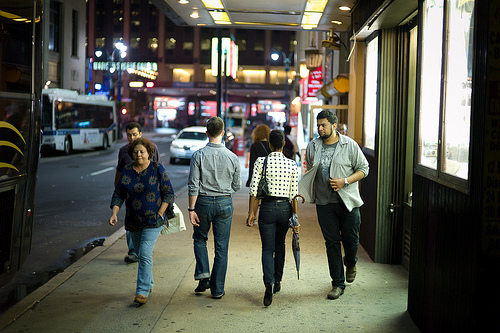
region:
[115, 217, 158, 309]
Person wearing blue pants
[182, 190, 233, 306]
Person wearing blue jeans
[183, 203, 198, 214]
Wrist watch on left wrist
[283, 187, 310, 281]
Woman carrying an umbrella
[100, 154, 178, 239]
Person wearing a blue sweater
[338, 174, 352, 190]
Silver watch on a man's wrist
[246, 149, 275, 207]
Woman wearing a purse on left shoulder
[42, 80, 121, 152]
White tour bus on a street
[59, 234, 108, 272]
Concrete curb on edge of sidewalk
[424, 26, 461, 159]
Light coming from inside a window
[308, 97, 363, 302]
man wearing a t shirt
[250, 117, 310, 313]
woman wearing white shirt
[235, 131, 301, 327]
woman wearing blue jeans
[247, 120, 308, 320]
woman holding an umbrella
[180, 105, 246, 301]
man wearing gray shirt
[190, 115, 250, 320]
man wearing blue jeans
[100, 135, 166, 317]
woman wearing blue shirt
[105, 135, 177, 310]
woman wearing blue jeans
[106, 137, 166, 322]
woman wearing brown shoes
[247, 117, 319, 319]
woman walking on sidewalk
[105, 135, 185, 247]
A woman with short hair.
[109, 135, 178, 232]
A woman wearing a long sleeve shirt.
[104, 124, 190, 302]
A woman wearing a pair of light blue jeans.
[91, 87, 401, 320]
People walking down a city sidewalk.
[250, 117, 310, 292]
A woman carrying an umbrella.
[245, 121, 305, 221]
A woman wearing a black and white shirt.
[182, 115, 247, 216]
A wristwatch on man's left wrist.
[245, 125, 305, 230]
A pocketbook over woman's left shoulder.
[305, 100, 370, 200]
Man wearing a silver wristwatch.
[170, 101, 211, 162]
A white vehicle on the side of the street.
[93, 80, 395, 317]
people walking on side walk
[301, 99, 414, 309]
man in t-shirt and jeans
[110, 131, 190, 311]
woman in blue sweater and jeans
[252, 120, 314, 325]
woman walking with umbrella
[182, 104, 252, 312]
man with blue shirt and jeans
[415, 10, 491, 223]
brightly lit store windows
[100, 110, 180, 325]
man walking behind woman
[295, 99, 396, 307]
man wearing two shirts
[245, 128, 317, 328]
woman with black hair walking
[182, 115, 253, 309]
white man wearing watch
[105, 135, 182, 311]
woman in blue jeans with short hair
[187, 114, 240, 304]
man in blue jeans walking away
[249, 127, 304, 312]
woman walking away, holding umbrella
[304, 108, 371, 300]
man in jeans walking forward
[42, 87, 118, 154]
bus stopped at bus stop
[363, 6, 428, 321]
doorway to unknown building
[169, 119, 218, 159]
white limousine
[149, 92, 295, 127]
unknown storefront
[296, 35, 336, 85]
streetlight attached to building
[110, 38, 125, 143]
lamp post streetlight